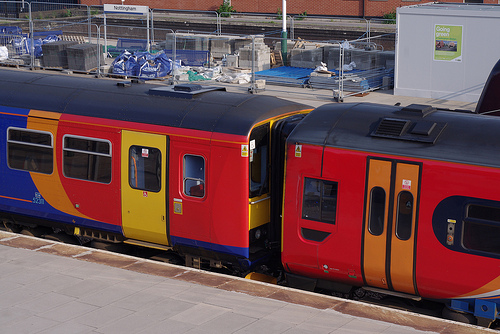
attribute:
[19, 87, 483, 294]
train — yellow, blue, long, short, stopped, heavy, still, red, orange, here, closer, close, moving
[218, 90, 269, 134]
roof — dark, black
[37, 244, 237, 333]
ground — brown, orange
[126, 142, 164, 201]
window — closed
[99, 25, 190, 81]
bags — blue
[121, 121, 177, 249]
door — closed